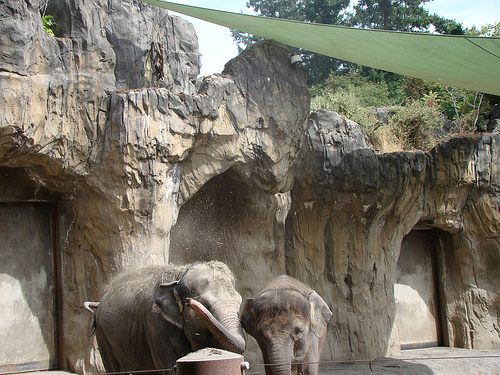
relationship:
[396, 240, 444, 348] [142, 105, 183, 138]
door in rocks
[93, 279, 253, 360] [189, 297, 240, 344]
elephant has trunk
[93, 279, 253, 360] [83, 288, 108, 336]
elephant has tail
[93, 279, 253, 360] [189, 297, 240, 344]
elephant waves trunk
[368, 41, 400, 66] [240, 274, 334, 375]
canopy over elephant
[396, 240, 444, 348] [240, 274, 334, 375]
door behind elephant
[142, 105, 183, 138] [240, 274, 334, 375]
rocks behind elephant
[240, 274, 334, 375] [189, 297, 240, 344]
elephant with trunk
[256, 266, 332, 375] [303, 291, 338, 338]
elephant with ears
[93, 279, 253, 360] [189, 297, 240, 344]
elephant upraised trunk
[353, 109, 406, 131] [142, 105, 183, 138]
plants over rocks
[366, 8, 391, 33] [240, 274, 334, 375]
trees over elephant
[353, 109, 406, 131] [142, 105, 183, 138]
plants in rocks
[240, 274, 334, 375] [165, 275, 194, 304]
elephant shooting dust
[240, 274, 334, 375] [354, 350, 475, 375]
elephant behind fence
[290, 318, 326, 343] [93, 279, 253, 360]
eye of elephant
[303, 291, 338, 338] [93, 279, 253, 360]
ears of elephant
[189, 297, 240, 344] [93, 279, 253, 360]
trunk of elephant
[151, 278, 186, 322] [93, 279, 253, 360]
ear of elephant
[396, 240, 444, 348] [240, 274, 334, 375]
door for elephant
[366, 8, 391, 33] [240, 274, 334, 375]
trees behind elephant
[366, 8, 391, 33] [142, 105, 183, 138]
trees above rocks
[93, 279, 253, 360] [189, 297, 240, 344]
elephant curled trunk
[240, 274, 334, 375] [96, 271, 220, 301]
elephant hairy back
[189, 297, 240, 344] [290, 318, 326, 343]
trunk blocking eye